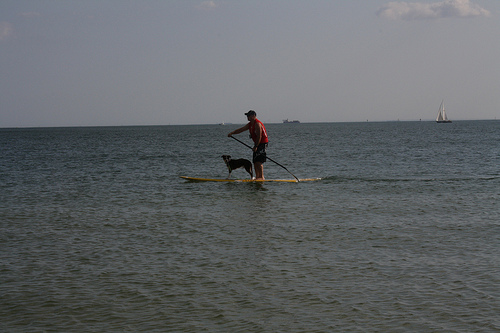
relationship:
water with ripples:
[103, 121, 122, 162] [369, 143, 416, 151]